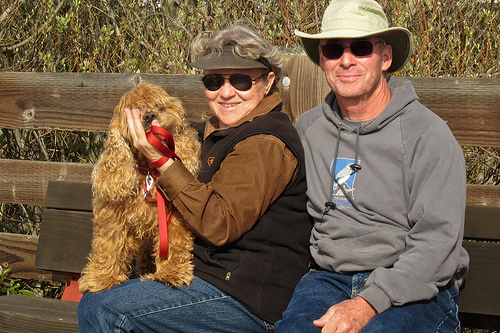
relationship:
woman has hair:
[70, 25, 307, 333] [185, 24, 292, 69]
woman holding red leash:
[70, 25, 307, 333] [145, 125, 175, 260]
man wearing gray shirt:
[275, 1, 470, 328] [291, 75, 471, 315]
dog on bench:
[75, 80, 204, 296] [10, 173, 492, 331]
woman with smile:
[70, 25, 307, 333] [213, 95, 247, 113]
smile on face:
[213, 95, 247, 113] [195, 59, 276, 133]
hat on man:
[295, 1, 413, 71] [275, 1, 470, 328]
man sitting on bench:
[275, 1, 470, 328] [2, 70, 498, 329]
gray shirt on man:
[291, 76, 471, 314] [275, 1, 470, 328]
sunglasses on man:
[307, 35, 384, 66] [275, 0, 470, 331]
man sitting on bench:
[275, 0, 470, 331] [0, 179, 499, 331]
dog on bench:
[75, 80, 204, 296] [2, 70, 498, 329]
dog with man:
[75, 80, 204, 296] [275, 1, 470, 328]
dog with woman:
[75, 80, 204, 296] [70, 25, 307, 333]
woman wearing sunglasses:
[70, 25, 307, 333] [190, 65, 262, 100]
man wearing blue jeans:
[275, 0, 470, 331] [287, 271, 442, 331]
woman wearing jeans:
[70, 25, 307, 333] [95, 267, 267, 331]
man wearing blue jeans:
[275, 0, 470, 331] [276, 272, 461, 332]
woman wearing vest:
[70, 25, 307, 333] [157, 91, 308, 306]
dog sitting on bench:
[66, 72, 206, 298] [2, 70, 498, 329]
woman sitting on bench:
[70, 25, 307, 333] [2, 70, 498, 329]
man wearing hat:
[275, 1, 470, 328] [287, 0, 416, 74]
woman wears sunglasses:
[70, 25, 307, 333] [198, 68, 259, 100]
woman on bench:
[70, 25, 307, 333] [10, 173, 492, 331]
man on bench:
[275, 0, 470, 331] [10, 173, 492, 331]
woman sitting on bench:
[70, 25, 307, 333] [0, 179, 499, 331]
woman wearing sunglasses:
[70, 25, 307, 333] [200, 70, 255, 94]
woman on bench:
[186, 18, 288, 122] [0, 172, 81, 321]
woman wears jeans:
[186, 18, 288, 122] [94, 295, 249, 332]